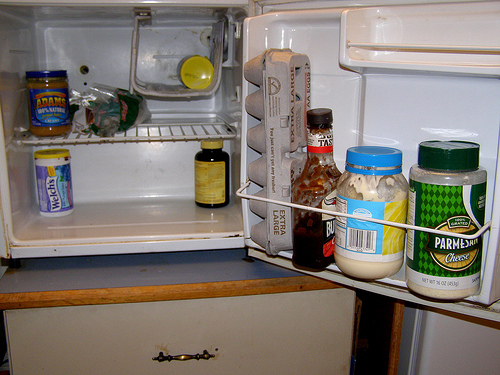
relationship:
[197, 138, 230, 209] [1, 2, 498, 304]
vitamins in fridge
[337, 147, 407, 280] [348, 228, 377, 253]
mayonnaise has barcode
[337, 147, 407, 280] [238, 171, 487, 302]
mayonnaise on door shelf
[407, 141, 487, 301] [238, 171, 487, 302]
parmesan cheese on door shelf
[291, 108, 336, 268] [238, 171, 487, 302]
barbeque sauce on door shelf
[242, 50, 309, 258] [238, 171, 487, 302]
eggs on door shelf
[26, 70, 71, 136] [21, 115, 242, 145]
sauce on top shelf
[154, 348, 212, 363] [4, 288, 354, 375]
handle attached to drawer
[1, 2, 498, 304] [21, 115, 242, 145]
fridge has top shelf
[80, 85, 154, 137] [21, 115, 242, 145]
bag on top shelf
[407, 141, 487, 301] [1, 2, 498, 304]
parmesan cheese in fridge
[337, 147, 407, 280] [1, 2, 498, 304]
mayonnaise in fridge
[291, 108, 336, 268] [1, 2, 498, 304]
barbeque sauce in fridge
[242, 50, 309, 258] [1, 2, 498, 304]
eggs in fridge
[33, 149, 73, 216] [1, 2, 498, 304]
welch's drink in fridge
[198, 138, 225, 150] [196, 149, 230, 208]
yellow lid on bottle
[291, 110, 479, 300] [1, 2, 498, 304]
condiments in fridge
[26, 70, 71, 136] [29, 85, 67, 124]
sauce has label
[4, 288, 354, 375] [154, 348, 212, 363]
drawer has handle